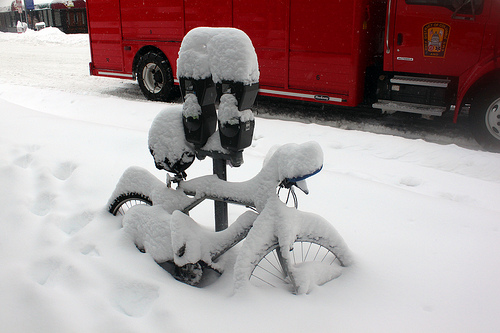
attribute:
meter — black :
[147, 50, 365, 282]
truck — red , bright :
[77, 4, 495, 124]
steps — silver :
[370, 72, 452, 118]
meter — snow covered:
[105, 17, 307, 205]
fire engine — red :
[82, 2, 497, 145]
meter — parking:
[78, 168, 362, 290]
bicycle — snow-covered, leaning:
[107, 152, 354, 296]